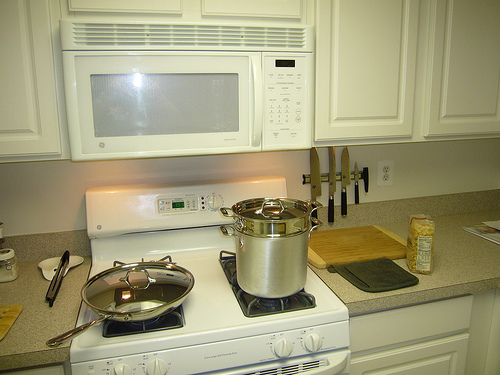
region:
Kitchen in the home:
[15, 1, 445, 373]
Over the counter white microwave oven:
[61, 12, 390, 171]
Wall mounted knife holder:
[296, 151, 396, 222]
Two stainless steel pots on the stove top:
[60, 181, 348, 326]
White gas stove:
[84, 184, 317, 374]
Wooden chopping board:
[311, 227, 428, 270]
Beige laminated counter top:
[451, 215, 499, 292]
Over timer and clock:
[152, 191, 237, 223]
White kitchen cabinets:
[313, 30, 498, 131]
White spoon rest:
[38, 252, 88, 309]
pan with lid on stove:
[41, 253, 196, 350]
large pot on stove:
[220, 187, 326, 321]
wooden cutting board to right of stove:
[300, 213, 410, 268]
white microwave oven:
[56, 17, 321, 164]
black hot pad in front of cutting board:
[323, 245, 427, 300]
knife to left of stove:
[32, 236, 86, 308]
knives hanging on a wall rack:
[300, 145, 377, 222]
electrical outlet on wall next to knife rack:
[376, 154, 397, 196]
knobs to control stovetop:
[260, 323, 333, 371]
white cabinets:
[311, 1, 497, 150]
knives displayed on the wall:
[301, 152, 377, 231]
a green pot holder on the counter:
[326, 258, 424, 300]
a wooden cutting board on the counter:
[311, 217, 412, 269]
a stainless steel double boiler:
[206, 184, 332, 314]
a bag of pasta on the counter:
[396, 203, 446, 277]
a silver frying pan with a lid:
[58, 253, 200, 340]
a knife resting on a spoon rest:
[32, 241, 82, 316]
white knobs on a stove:
[255, 325, 348, 371]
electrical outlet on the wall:
[373, 162, 403, 190]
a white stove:
[67, 175, 340, 373]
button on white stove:
[298, 329, 340, 351]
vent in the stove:
[268, 359, 312, 370]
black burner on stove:
[227, 274, 343, 331]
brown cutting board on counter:
[310, 209, 428, 276]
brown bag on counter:
[391, 193, 453, 286]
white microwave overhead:
[58, 13, 335, 166]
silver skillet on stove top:
[73, 248, 213, 316]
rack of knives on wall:
[312, 147, 379, 209]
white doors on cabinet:
[304, 10, 430, 127]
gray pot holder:
[322, 252, 449, 315]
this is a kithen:
[3, 5, 498, 372]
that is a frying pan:
[38, 259, 198, 351]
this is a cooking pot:
[219, 195, 326, 317]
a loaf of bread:
[403, 212, 437, 281]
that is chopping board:
[298, 222, 406, 260]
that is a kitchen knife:
[306, 142, 324, 231]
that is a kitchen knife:
[325, 142, 340, 224]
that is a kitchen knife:
[349, 162, 361, 217]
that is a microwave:
[66, 52, 268, 156]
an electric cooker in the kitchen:
[78, 168, 352, 373]